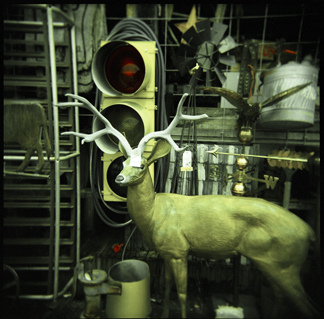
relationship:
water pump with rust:
[78, 254, 121, 316] [109, 281, 127, 297]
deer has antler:
[61, 92, 320, 318] [52, 87, 140, 162]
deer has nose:
[61, 92, 320, 318] [114, 175, 124, 182]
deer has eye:
[61, 92, 320, 318] [120, 162, 124, 167]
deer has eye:
[61, 92, 320, 318] [138, 162, 144, 168]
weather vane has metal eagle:
[197, 62, 318, 197] [192, 75, 314, 132]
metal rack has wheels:
[2, 3, 81, 301] [20, 292, 110, 317]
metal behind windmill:
[44, 3, 81, 301] [181, 18, 247, 90]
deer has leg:
[61, 92, 320, 318] [172, 256, 186, 315]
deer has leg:
[61, 92, 320, 318] [163, 259, 172, 317]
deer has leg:
[61, 92, 320, 318] [251, 248, 320, 315]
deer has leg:
[61, 92, 320, 318] [276, 268, 314, 315]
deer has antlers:
[33, 80, 322, 311] [49, 82, 214, 163]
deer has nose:
[61, 92, 320, 318] [114, 174, 122, 181]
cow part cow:
[3, 98, 50, 172] [3, 98, 50, 172]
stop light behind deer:
[90, 41, 157, 203] [61, 92, 320, 318]